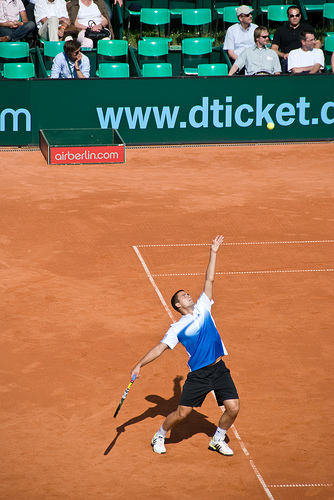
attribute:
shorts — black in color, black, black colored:
[179, 357, 239, 410]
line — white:
[130, 244, 180, 326]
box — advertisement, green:
[40, 128, 127, 163]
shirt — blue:
[163, 293, 231, 374]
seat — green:
[141, 58, 177, 77]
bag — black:
[88, 19, 111, 39]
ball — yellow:
[265, 117, 276, 132]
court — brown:
[2, 145, 331, 496]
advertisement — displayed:
[2, 78, 334, 150]